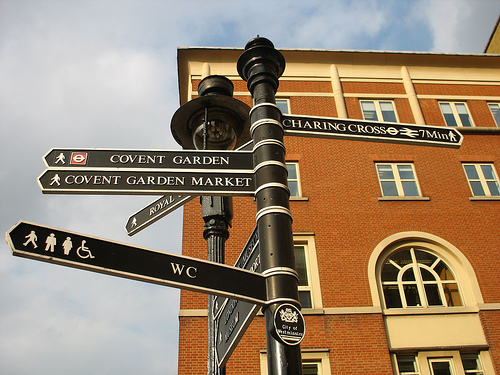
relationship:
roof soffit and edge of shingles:
[179, 47, 496, 69] [268, 50, 463, 88]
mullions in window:
[373, 240, 462, 312] [349, 224, 498, 374]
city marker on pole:
[237, 128, 358, 238] [230, 31, 305, 374]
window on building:
[463, 163, 499, 198] [174, 46, 496, 372]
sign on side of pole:
[175, 46, 322, 193] [226, 100, 303, 370]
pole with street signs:
[236, 36, 305, 375] [59, 149, 259, 190]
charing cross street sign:
[289, 117, 464, 150] [36, 32, 461, 363]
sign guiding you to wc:
[7, 209, 261, 312] [167, 257, 199, 280]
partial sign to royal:
[109, 187, 201, 247] [125, 192, 190, 302]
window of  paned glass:
[462, 159, 498, 196] [454, 156, 497, 206]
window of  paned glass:
[371, 160, 423, 195] [444, 97, 484, 137]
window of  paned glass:
[358, 95, 398, 123] [362, 95, 397, 114]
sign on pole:
[44, 215, 267, 307] [238, 192, 290, 311]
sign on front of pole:
[267, 297, 308, 350] [232, 30, 311, 371]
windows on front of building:
[356, 100, 497, 202] [174, 46, 496, 372]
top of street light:
[183, 68, 238, 140] [207, 60, 237, 122]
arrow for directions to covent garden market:
[39, 160, 246, 204] [115, 181, 169, 251]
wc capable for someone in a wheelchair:
[162, 254, 203, 281] [73, 235, 97, 265]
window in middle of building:
[370, 229, 486, 311] [174, 46, 496, 372]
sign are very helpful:
[5, 222, 267, 304] [35, 143, 279, 254]